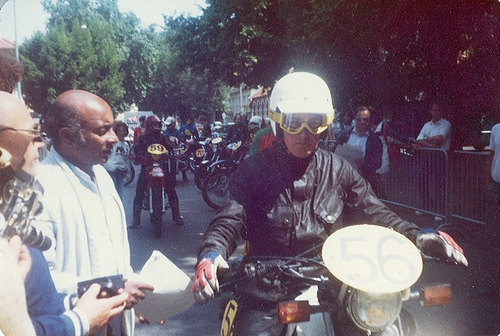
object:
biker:
[191, 67, 467, 336]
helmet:
[268, 70, 335, 140]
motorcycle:
[197, 239, 460, 335]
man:
[31, 89, 158, 335]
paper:
[128, 250, 199, 326]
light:
[344, 287, 413, 333]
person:
[129, 114, 187, 228]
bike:
[142, 142, 172, 237]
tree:
[17, 0, 151, 141]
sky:
[0, 0, 212, 48]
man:
[413, 99, 455, 220]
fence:
[369, 139, 498, 236]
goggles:
[268, 107, 335, 135]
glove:
[190, 249, 228, 304]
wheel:
[145, 184, 172, 239]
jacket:
[201, 147, 425, 292]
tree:
[163, 0, 377, 93]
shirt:
[59, 153, 131, 335]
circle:
[320, 223, 423, 293]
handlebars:
[200, 247, 330, 286]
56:
[341, 234, 414, 285]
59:
[150, 143, 164, 152]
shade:
[112, 161, 266, 270]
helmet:
[143, 114, 163, 133]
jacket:
[28, 156, 139, 336]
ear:
[58, 128, 77, 148]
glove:
[414, 230, 468, 268]